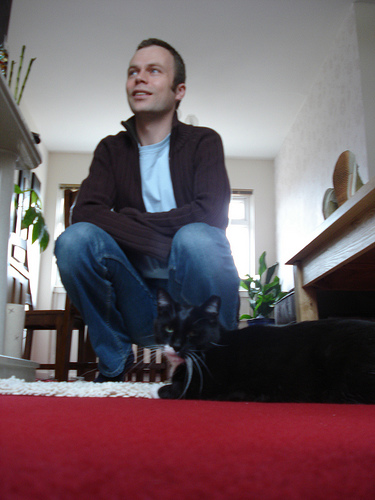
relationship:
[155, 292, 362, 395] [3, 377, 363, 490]
cat lays floor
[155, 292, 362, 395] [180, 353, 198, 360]
cat has spot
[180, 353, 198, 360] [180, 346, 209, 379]
spot on mouth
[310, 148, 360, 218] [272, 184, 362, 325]
plates on table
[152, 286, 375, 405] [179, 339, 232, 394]
cat has whiskers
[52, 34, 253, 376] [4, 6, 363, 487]
guy in room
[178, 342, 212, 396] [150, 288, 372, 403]
whiskers on cat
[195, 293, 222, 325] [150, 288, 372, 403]
ear of cat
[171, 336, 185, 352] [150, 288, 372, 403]
nose of cat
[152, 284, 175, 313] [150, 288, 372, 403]
ear of cat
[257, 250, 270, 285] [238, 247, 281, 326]
leaf of plant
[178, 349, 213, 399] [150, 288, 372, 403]
whiskers on cat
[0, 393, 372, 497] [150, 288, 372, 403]
carpet under cat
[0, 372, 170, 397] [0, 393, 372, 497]
cloth on carpet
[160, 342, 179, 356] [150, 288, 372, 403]
patch on cat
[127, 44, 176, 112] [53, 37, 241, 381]
face of guy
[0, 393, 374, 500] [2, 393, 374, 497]
carpet on top of rug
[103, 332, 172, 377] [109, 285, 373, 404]
whiskers of a cat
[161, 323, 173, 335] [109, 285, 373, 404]
eye of cat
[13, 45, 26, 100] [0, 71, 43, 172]
bamboo on a mantle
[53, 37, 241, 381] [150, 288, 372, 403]
guy kneeling behind a cat